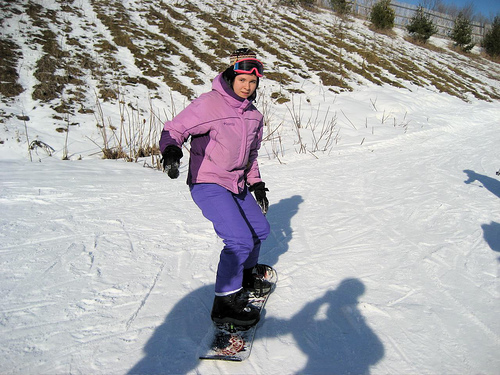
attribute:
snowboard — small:
[198, 262, 279, 362]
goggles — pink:
[232, 56, 264, 77]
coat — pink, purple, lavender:
[160, 73, 265, 195]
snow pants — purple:
[188, 183, 271, 296]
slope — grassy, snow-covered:
[0, 0, 499, 158]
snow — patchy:
[0, 0, 499, 133]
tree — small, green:
[406, 4, 438, 41]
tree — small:
[370, 0, 394, 31]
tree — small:
[449, 11, 477, 53]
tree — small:
[481, 13, 499, 63]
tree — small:
[330, 0, 353, 21]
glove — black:
[162, 144, 185, 180]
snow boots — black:
[211, 267, 273, 328]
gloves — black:
[160, 143, 270, 214]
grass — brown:
[0, 0, 499, 162]